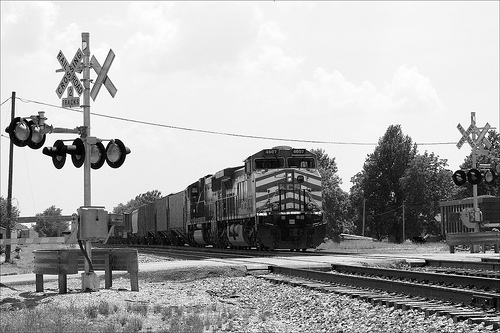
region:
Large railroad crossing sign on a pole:
[38, 37, 92, 116]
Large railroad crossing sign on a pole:
[86, 43, 117, 107]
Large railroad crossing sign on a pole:
[445, 114, 480, 164]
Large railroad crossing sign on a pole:
[473, 119, 499, 155]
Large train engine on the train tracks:
[192, 146, 357, 260]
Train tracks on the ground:
[290, 256, 482, 321]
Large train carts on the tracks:
[119, 196, 190, 250]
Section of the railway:
[219, 237, 409, 332]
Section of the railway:
[101, 211, 239, 313]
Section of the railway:
[32, 220, 152, 330]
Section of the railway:
[212, 135, 347, 285]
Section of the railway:
[316, 157, 421, 324]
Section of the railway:
[22, 131, 154, 328]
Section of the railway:
[135, 143, 267, 313]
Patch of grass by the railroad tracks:
[18, 299, 64, 329]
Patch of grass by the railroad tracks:
[71, 294, 99, 327]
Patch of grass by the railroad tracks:
[95, 288, 114, 315]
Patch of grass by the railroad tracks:
[121, 295, 153, 317]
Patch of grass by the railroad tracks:
[153, 296, 198, 332]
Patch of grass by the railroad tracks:
[83, 311, 136, 331]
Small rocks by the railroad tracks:
[218, 275, 268, 302]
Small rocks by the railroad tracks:
[270, 286, 320, 313]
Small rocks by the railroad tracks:
[315, 291, 355, 328]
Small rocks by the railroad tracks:
[362, 306, 403, 331]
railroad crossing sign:
[54, 47, 87, 97]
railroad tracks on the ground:
[266, 254, 498, 329]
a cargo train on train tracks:
[123, 146, 326, 250]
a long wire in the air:
[9, 91, 493, 150]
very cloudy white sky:
[126, 2, 494, 105]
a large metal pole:
[77, 29, 99, 291]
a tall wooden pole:
[3, 92, 23, 262]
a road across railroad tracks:
[1, 249, 498, 286]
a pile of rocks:
[278, 288, 325, 322]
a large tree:
[351, 124, 452, 246]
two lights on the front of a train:
[285, 170, 294, 182]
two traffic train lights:
[88, 137, 131, 167]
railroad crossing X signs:
[55, 49, 120, 101]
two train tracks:
[261, 257, 498, 329]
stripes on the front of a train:
[258, 170, 323, 213]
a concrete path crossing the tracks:
[1, 232, 447, 287]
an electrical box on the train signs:
[76, 205, 110, 246]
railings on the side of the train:
[214, 197, 241, 222]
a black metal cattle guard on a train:
[274, 180, 306, 225]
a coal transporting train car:
[441, 193, 498, 243]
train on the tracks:
[103, 135, 334, 257]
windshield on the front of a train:
[252, 153, 317, 170]